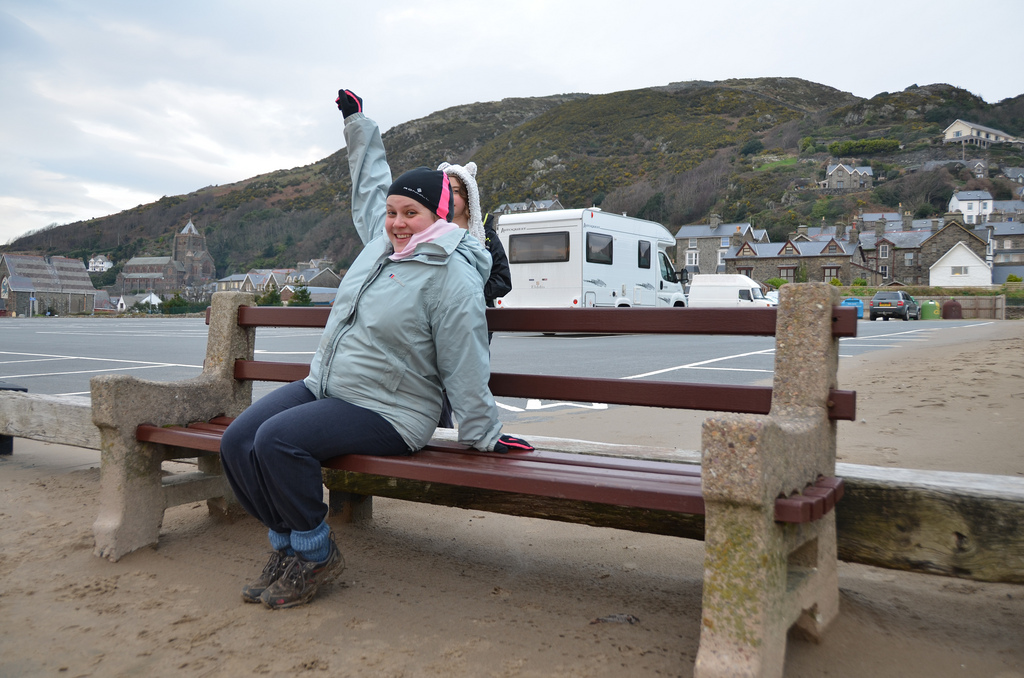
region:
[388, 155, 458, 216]
Black hat on person's head.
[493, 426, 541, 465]
Person wearing glove on hand.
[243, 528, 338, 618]
Person wearing black tennis shoes.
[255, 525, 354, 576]
Person wearing blue socks.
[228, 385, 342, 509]
Person wearing blue pants.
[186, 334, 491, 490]
Person sitting on bench.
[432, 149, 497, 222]
Person wearing hat with ears.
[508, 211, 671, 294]
White vehicle parked in lot.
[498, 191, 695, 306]
van is white in color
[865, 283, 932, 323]
car is grey in color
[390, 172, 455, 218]
girl is wearing hat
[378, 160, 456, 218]
hat is black and pink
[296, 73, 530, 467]
coat is blue in color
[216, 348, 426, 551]
girl is wearing pants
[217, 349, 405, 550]
pants are blue in color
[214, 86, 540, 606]
woman in light grey jacket and black hat with pink tassel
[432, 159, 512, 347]
person wearing white hat with fuzzy ears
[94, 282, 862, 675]
red wodden bench with stone arm rests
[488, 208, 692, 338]
white camper truck with large rear window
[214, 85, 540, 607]
woman with dark blue sweatpants sitting on bench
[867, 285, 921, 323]
dark gray car with yellow license plate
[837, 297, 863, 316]
light blue container next to grey car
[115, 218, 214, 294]
brown building with pointy silver steeple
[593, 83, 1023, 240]
bushy mountain with houses on it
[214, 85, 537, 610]
Girl in jacket sitting on bench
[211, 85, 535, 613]
Young woman wearing gray jacket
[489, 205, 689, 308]
White camper truck parked in parking lot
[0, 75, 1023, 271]
Small mountain with deciduous and evergreen trees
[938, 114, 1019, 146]
White house high on mountainside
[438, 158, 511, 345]
Girl wearing white hat with ears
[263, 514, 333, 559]
Loose blue socks gathered around girl's ankles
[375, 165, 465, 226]
woman wearing a blue hat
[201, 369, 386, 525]
woman wearing blue pants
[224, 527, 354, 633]
woman wearing brown shoes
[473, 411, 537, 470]
woman wearing black gloves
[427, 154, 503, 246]
girl wearing a white hat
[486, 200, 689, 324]
white camper in the lot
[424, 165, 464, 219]
pink stripe on the hat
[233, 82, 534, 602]
woman sitting on the bench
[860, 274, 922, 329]
car in the parking lot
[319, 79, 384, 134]
woman wearing a black glove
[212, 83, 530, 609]
Girl holding her hand up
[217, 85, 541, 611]
Girl in jacket sitting down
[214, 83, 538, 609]
Girl wearing a cap and gloves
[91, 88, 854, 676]
Girl sitting on a brown bench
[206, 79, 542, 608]
Girl sitting with another behind her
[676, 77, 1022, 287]
Homes on the side of a hill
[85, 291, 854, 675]
Brown bench on the sand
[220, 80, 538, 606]
Female in warm clothing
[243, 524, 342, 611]
Dark shoes with blue socks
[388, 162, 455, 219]
Pink and black beanie cap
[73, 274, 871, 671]
wood and stone bench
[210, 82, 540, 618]
woman sitting on bench with one arm extended in the air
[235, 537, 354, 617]
pair of black shoes on person sitting on bench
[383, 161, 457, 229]
black hat with pink accent on person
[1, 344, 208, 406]
white line drawn on parking lot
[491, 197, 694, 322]
white mini trailer parked in parking lot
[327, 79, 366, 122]
one red and black glove on person on bench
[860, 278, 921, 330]
grey car parked in parking lot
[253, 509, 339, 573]
pair of light blue socks on person on the bench